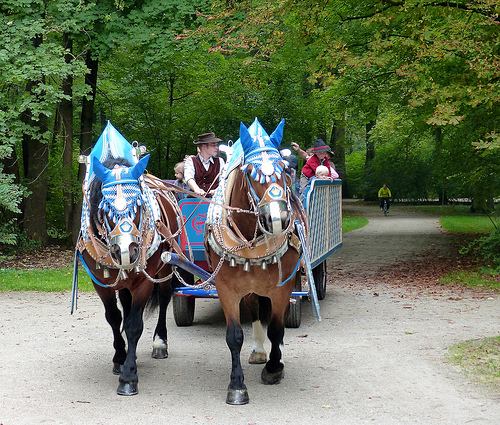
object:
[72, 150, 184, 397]
horse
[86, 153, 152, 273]
head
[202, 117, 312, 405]
horse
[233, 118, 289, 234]
head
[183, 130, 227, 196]
man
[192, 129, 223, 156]
head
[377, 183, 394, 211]
man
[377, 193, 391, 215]
bike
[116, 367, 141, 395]
hoof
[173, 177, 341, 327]
wagon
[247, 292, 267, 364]
leg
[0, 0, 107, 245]
tree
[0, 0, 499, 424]
background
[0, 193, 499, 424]
path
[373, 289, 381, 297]
leaves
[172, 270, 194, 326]
wheel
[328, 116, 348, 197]
trunk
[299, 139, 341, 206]
child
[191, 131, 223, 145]
hat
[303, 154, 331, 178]
sweater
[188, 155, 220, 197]
jacket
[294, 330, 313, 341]
spot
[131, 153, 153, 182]
ear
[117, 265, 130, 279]
bell